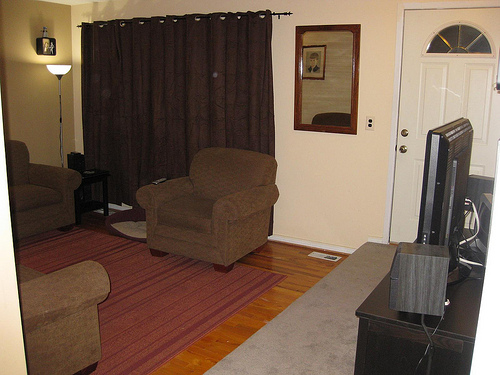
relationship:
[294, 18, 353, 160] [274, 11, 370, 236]
mirror on wall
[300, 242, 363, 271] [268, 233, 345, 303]
vent on floor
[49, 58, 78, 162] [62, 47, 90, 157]
lamp in corner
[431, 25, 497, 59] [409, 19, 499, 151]
window on door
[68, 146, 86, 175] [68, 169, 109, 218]
speaker on stand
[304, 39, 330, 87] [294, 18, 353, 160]
picture in mirror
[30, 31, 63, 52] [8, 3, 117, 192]
oleo on wall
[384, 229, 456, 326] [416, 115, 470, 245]
speaker by television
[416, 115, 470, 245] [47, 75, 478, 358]
television in living room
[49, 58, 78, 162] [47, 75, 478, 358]
lamp in living room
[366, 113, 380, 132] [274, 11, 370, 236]
switch on wall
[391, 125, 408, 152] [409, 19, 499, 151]
deadbolt on door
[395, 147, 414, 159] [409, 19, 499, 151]
doorknob on door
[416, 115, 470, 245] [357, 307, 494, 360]
flatscreen on countertop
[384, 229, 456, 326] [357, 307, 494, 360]
speaker on countertop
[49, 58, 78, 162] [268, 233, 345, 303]
lamp on floor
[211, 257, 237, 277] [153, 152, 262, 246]
legs on chair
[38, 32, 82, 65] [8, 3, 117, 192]
box on wall